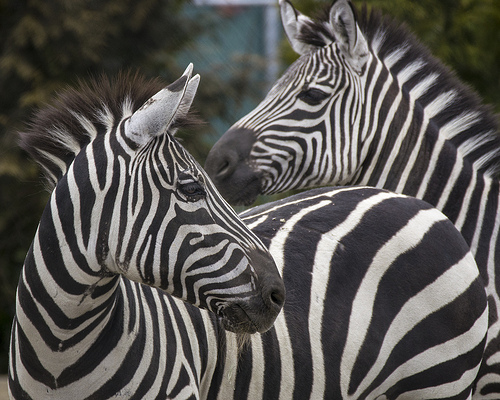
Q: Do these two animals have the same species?
A: Yes, all the animals are zebras.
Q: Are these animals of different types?
A: No, all the animals are zebras.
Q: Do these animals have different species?
A: No, all the animals are zebras.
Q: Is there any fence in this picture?
A: Yes, there is a fence.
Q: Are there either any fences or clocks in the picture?
A: Yes, there is a fence.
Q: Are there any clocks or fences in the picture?
A: Yes, there is a fence.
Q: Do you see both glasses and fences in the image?
A: No, there is a fence but no glasses.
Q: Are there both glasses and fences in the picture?
A: No, there is a fence but no glasses.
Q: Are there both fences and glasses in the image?
A: No, there is a fence but no glasses.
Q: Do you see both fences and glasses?
A: No, there is a fence but no glasses.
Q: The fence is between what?
A: The fence is between the trees.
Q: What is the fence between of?
A: The fence is between the trees.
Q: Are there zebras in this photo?
A: Yes, there is a zebra.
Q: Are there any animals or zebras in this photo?
A: Yes, there is a zebra.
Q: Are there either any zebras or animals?
A: Yes, there is a zebra.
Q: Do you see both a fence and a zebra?
A: Yes, there are both a zebra and a fence.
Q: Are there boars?
A: No, there are no boars.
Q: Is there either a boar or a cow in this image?
A: No, there are no boars or cows.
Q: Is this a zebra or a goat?
A: This is a zebra.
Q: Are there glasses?
A: No, there are no glasses.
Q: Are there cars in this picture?
A: No, there are no cars.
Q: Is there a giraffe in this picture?
A: No, there are no giraffes.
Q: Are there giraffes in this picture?
A: No, there are no giraffes.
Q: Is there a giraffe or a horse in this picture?
A: No, there are no giraffes or horses.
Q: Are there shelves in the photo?
A: No, there are no shelves.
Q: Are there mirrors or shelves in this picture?
A: No, there are no shelves or mirrors.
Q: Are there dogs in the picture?
A: No, there are no dogs.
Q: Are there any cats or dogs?
A: No, there are no dogs or cats.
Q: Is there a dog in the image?
A: No, there are no dogs.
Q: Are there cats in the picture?
A: No, there are no cats.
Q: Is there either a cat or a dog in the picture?
A: No, there are no cats or dogs.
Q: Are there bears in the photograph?
A: No, there are no bears.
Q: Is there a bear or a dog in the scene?
A: No, there are no bears or dogs.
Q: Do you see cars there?
A: No, there are no cars.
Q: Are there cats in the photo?
A: No, there are no cats.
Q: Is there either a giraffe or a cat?
A: No, there are no cats or giraffes.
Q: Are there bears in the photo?
A: No, there are no bears.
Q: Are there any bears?
A: No, there are no bears.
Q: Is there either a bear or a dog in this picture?
A: No, there are no bears or dogs.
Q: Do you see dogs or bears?
A: No, there are no bears or dogs.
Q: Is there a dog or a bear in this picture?
A: No, there are no bears or dogs.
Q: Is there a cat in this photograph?
A: No, there are no cats.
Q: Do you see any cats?
A: No, there are no cats.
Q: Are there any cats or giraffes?
A: No, there are no cats or giraffes.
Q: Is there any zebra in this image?
A: Yes, there is a zebra.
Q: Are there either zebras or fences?
A: Yes, there is a zebra.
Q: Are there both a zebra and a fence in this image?
A: Yes, there are both a zebra and a fence.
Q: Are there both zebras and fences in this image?
A: Yes, there are both a zebra and a fence.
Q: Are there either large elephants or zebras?
A: Yes, there is a large zebra.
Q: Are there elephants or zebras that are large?
A: Yes, the zebra is large.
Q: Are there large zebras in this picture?
A: Yes, there is a large zebra.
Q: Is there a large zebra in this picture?
A: Yes, there is a large zebra.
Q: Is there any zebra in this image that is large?
A: Yes, there is a zebra that is large.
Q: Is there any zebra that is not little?
A: Yes, there is a large zebra.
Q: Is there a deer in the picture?
A: No, there is no deer.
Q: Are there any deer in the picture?
A: No, there are no deer.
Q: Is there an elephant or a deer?
A: No, there are no deer or elephants.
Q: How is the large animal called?
A: The animal is a zebra.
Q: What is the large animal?
A: The animal is a zebra.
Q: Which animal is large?
A: The animal is a zebra.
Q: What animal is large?
A: The animal is a zebra.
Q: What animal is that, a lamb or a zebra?
A: That is a zebra.